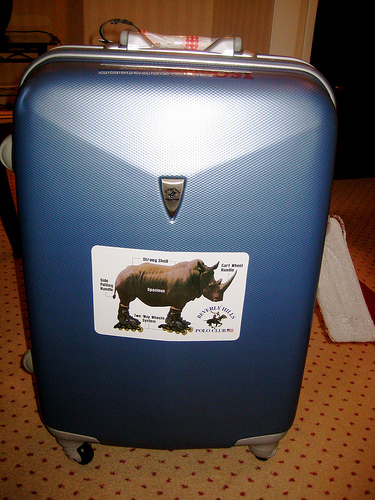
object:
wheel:
[73, 441, 95, 465]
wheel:
[255, 454, 267, 461]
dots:
[166, 477, 172, 484]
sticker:
[91, 244, 250, 342]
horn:
[220, 270, 237, 294]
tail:
[112, 283, 117, 299]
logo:
[159, 174, 187, 223]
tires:
[73, 441, 94, 465]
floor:
[0, 168, 375, 497]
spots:
[180, 484, 188, 489]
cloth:
[316, 215, 375, 344]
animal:
[113, 258, 237, 329]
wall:
[0, 0, 319, 113]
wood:
[298, 10, 341, 59]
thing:
[0, 133, 20, 218]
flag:
[227, 328, 234, 332]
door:
[308, 0, 375, 178]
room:
[0, 0, 375, 500]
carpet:
[0, 172, 375, 500]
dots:
[300, 453, 305, 459]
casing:
[46, 425, 100, 462]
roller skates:
[113, 304, 143, 333]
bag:
[12, 44, 336, 466]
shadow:
[13, 260, 32, 350]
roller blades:
[158, 307, 194, 336]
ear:
[197, 261, 206, 273]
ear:
[210, 261, 220, 271]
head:
[190, 261, 236, 302]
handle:
[118, 28, 242, 53]